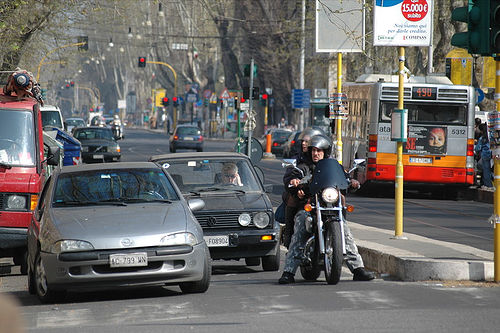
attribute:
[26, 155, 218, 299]
grey car — small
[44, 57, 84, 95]
circle — red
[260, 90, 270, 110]
light — suspended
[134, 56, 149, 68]
traffic light — suspended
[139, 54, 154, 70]
light — red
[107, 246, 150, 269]
license plate — white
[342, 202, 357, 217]
light — orange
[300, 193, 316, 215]
light — orange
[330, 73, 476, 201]
bus — red, silver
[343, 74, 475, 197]
bus — large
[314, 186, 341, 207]
headlight — round, lit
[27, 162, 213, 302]
car — grey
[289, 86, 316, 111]
sign — road sign, blue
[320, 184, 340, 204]
headlight — white, round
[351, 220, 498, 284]
cement median — grey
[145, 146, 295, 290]
car — black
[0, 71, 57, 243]
truck — red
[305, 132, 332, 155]
helmet — black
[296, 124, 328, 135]
helmet — black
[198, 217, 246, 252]
plate — white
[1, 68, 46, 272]
vehicle — large, red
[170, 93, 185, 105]
stop light — red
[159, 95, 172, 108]
stop light — red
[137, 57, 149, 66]
stop light — red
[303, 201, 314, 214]
light — orange